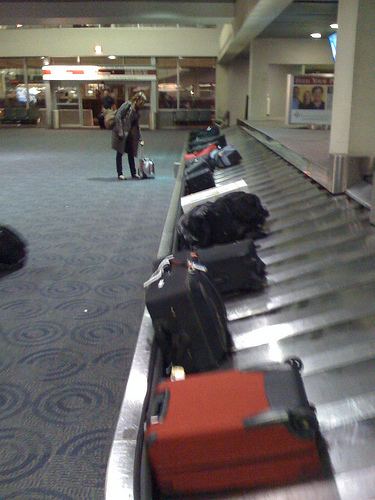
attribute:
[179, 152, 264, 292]
bunch of luggage — waiting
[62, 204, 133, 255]
carpet — dark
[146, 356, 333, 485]
bag — red, black, orange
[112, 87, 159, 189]
woman — waiting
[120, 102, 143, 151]
coat — large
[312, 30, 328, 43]
light — on, small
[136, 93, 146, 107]
hair — light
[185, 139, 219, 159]
luggage — red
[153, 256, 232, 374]
luggage — standing, black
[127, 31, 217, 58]
wall — off-white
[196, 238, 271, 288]
suitcase — black, canvas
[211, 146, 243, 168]
suitcase — light blue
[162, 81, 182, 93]
sign — lit up